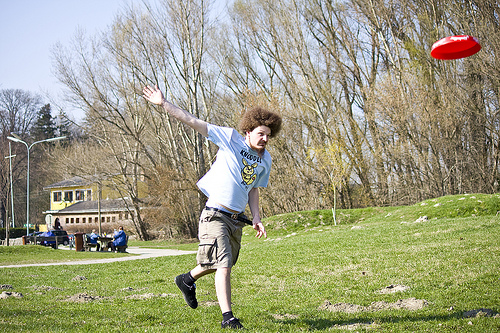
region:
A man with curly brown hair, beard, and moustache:
[217, 101, 297, 166]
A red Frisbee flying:
[420, 22, 482, 87]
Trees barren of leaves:
[60, 71, 215, 158]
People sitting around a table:
[80, 220, 160, 255]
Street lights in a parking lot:
[2, 106, 79, 186]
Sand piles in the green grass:
[315, 280, 432, 325]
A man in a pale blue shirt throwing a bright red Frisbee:
[193, 115, 279, 209]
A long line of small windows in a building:
[54, 206, 136, 231]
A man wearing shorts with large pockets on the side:
[188, 194, 269, 289]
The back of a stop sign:
[38, 210, 62, 232]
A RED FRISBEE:
[423, 25, 484, 65]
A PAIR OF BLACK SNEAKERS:
[170, 260, 250, 327]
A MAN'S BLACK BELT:
[196, 190, 261, 230]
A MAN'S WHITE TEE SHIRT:
[192, 110, 273, 211]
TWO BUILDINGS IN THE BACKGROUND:
[35, 161, 175, 242]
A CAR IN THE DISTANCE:
[27, 225, 72, 250]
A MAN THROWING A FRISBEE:
[111, 12, 478, 323]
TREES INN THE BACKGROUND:
[279, 30, 444, 203]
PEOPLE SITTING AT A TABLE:
[78, 226, 139, 255]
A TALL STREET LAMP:
[1, 125, 75, 246]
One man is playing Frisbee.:
[192, 87, 302, 290]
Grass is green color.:
[308, 234, 387, 266]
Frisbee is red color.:
[427, 33, 477, 65]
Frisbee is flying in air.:
[423, 27, 478, 75]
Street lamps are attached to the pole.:
[5, 121, 56, 210]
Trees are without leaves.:
[143, 36, 387, 118]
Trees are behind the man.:
[171, 48, 398, 118]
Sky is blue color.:
[7, 16, 83, 46]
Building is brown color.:
[49, 183, 144, 247]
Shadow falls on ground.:
[258, 286, 492, 328]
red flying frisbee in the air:
[430, 18, 470, 67]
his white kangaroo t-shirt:
[225, 137, 288, 223]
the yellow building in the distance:
[39, 172, 124, 239]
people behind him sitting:
[77, 212, 133, 272]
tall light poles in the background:
[16, 128, 56, 246]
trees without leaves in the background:
[92, 20, 494, 192]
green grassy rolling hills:
[267, 190, 483, 302]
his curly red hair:
[244, 93, 282, 163]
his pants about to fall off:
[190, 202, 268, 295]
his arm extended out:
[142, 61, 235, 156]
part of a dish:
[433, 35, 467, 57]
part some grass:
[373, 224, 431, 272]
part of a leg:
[212, 280, 238, 295]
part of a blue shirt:
[205, 167, 234, 205]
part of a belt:
[238, 213, 253, 225]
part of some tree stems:
[374, 166, 451, 200]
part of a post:
[10, 177, 42, 229]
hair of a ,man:
[254, 112, 286, 123]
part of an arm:
[141, 102, 173, 119]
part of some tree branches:
[164, 55, 212, 93]